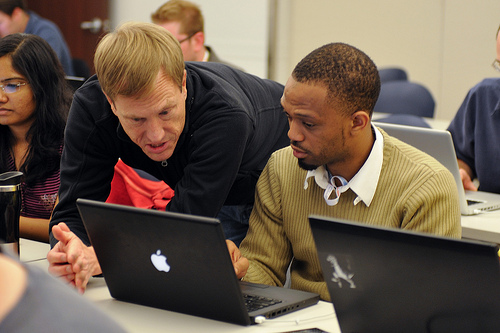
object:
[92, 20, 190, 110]
hair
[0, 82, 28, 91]
glasses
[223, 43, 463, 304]
man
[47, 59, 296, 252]
shirt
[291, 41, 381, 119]
hair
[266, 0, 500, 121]
wall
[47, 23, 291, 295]
man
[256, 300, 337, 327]
cable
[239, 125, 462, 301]
sweater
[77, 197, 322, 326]
computer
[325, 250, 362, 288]
logo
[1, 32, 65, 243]
woman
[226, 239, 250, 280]
hands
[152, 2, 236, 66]
man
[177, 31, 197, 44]
glasses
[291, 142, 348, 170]
beard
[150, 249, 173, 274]
icon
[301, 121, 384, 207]
collar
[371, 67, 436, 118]
chair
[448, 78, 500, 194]
shirt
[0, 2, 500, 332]
photo